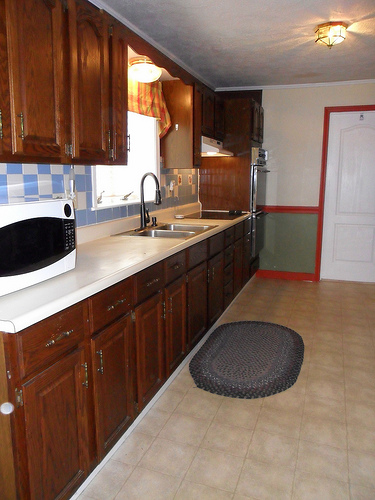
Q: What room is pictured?
A: It is a kitchen.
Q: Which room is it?
A: It is a kitchen.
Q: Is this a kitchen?
A: Yes, it is a kitchen.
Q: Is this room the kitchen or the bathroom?
A: It is the kitchen.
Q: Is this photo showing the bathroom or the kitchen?
A: It is showing the kitchen.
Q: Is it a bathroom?
A: No, it is a kitchen.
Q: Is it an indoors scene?
A: Yes, it is indoors.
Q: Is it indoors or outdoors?
A: It is indoors.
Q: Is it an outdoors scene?
A: No, it is indoors.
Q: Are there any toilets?
A: No, there are no toilets.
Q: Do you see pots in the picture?
A: No, there are no pots.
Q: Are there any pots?
A: No, there are no pots.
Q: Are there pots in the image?
A: No, there are no pots.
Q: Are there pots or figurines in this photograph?
A: No, there are no pots or figurines.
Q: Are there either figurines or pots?
A: No, there are no pots or figurines.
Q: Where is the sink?
A: The sink is in the kitchen.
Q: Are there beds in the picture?
A: No, there are no beds.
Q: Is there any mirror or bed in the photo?
A: No, there are no beds or mirrors.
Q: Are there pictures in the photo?
A: No, there are no pictures.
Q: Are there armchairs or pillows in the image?
A: No, there are no pillows or armchairs.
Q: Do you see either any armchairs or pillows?
A: No, there are no pillows or armchairs.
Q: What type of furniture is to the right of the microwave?
A: The piece of furniture is a drawer.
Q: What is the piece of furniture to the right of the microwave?
A: The piece of furniture is a drawer.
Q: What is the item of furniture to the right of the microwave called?
A: The piece of furniture is a drawer.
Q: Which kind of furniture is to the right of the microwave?
A: The piece of furniture is a drawer.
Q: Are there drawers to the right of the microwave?
A: Yes, there is a drawer to the right of the microwave.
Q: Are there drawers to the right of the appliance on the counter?
A: Yes, there is a drawer to the right of the microwave.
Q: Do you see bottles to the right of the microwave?
A: No, there is a drawer to the right of the microwave.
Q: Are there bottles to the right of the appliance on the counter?
A: No, there is a drawer to the right of the microwave.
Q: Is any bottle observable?
A: No, there are no bottles.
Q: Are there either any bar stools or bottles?
A: No, there are no bottles or bar stools.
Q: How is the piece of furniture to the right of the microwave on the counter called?
A: The piece of furniture is a drawer.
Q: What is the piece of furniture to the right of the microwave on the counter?
A: The piece of furniture is a drawer.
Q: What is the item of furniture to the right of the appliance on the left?
A: The piece of furniture is a drawer.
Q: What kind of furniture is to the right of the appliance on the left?
A: The piece of furniture is a drawer.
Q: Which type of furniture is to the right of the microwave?
A: The piece of furniture is a drawer.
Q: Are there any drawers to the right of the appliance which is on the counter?
A: Yes, there is a drawer to the right of the microwave.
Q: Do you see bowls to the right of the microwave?
A: No, there is a drawer to the right of the microwave.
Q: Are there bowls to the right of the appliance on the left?
A: No, there is a drawer to the right of the microwave.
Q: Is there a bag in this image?
A: No, there are no bags.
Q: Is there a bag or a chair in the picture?
A: No, there are no bags or chairs.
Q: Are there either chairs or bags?
A: No, there are no bags or chairs.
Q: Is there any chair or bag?
A: No, there are no bags or chairs.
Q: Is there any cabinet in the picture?
A: Yes, there is a cabinet.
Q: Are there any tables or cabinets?
A: Yes, there is a cabinet.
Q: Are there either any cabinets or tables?
A: Yes, there is a cabinet.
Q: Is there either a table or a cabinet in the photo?
A: Yes, there is a cabinet.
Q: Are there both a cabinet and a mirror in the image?
A: No, there is a cabinet but no mirrors.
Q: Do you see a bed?
A: No, there are no beds.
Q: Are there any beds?
A: No, there are no beds.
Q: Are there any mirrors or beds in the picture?
A: No, there are no beds or mirrors.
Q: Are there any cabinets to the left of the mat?
A: Yes, there is a cabinet to the left of the mat.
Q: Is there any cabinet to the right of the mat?
A: No, the cabinet is to the left of the mat.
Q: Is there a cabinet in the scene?
A: Yes, there is a cabinet.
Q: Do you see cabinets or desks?
A: Yes, there is a cabinet.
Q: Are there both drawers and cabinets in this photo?
A: Yes, there are both a cabinet and a drawer.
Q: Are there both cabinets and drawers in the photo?
A: Yes, there are both a cabinet and a drawer.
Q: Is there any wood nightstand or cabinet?
A: Yes, there is a wood cabinet.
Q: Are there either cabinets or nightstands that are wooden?
A: Yes, the cabinet is wooden.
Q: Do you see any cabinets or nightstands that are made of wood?
A: Yes, the cabinet is made of wood.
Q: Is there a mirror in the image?
A: No, there are no mirrors.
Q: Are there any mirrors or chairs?
A: No, there are no mirrors or chairs.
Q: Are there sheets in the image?
A: No, there are no sheets.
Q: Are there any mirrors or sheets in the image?
A: No, there are no sheets or mirrors.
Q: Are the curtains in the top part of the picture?
A: Yes, the curtains are in the top of the image.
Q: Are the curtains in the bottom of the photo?
A: No, the curtains are in the top of the image.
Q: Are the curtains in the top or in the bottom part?
A: The curtains are in the top of the image.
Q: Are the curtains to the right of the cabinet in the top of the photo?
A: Yes, the curtains are to the right of the cabinet.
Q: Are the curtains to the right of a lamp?
A: No, the curtains are to the right of the cabinet.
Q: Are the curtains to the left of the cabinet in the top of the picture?
A: No, the curtains are to the right of the cabinet.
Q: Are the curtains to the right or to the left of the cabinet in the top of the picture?
A: The curtains are to the right of the cabinet.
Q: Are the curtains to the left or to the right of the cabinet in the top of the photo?
A: The curtains are to the right of the cabinet.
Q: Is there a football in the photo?
A: No, there are no footballs.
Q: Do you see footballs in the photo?
A: No, there are no footballs.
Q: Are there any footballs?
A: No, there are no footballs.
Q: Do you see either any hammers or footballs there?
A: No, there are no footballs or hammers.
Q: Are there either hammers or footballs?
A: No, there are no footballs or hammers.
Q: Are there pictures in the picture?
A: No, there are no pictures.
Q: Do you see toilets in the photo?
A: No, there are no toilets.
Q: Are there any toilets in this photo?
A: No, there are no toilets.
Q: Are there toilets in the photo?
A: No, there are no toilets.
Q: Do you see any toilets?
A: No, there are no toilets.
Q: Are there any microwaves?
A: Yes, there is a microwave.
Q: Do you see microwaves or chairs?
A: Yes, there is a microwave.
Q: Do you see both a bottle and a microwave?
A: No, there is a microwave but no bottles.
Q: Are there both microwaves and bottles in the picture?
A: No, there is a microwave but no bottles.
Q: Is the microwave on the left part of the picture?
A: Yes, the microwave is on the left of the image.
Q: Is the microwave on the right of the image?
A: No, the microwave is on the left of the image.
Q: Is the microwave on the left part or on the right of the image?
A: The microwave is on the left of the image.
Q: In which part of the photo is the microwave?
A: The microwave is on the left of the image.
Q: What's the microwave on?
A: The microwave is on the counter.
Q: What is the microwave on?
A: The microwave is on the counter.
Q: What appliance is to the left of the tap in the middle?
A: The appliance is a microwave.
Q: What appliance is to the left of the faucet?
A: The appliance is a microwave.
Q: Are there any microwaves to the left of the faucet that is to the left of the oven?
A: Yes, there is a microwave to the left of the faucet.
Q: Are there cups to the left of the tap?
A: No, there is a microwave to the left of the tap.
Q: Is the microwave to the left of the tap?
A: Yes, the microwave is to the left of the tap.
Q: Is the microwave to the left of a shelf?
A: No, the microwave is to the left of the tap.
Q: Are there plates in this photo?
A: No, there are no plates.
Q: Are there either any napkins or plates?
A: No, there are no plates or napkins.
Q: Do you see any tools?
A: No, there are no tools.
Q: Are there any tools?
A: No, there are no tools.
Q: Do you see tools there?
A: No, there are no tools.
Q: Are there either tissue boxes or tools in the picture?
A: No, there are no tools or tissue boxes.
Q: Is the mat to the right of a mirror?
A: No, the mat is to the right of a cabinet.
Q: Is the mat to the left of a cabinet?
A: No, the mat is to the right of a cabinet.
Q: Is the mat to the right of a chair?
A: No, the mat is to the right of a cabinet.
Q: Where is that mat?
A: The mat is on the floor.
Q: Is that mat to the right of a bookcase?
A: No, the mat is to the right of a cabinet.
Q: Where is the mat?
A: The mat is on the floor.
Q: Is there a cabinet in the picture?
A: Yes, there is a cabinet.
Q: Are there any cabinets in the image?
A: Yes, there is a cabinet.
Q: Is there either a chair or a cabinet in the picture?
A: Yes, there is a cabinet.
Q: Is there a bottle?
A: No, there are no bottles.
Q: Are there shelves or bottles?
A: No, there are no bottles or shelves.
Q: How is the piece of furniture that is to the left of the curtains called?
A: The piece of furniture is a cabinet.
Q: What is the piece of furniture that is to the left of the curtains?
A: The piece of furniture is a cabinet.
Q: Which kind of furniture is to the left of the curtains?
A: The piece of furniture is a cabinet.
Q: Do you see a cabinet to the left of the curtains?
A: Yes, there is a cabinet to the left of the curtains.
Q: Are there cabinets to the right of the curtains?
A: No, the cabinet is to the left of the curtains.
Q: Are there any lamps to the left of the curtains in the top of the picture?
A: No, there is a cabinet to the left of the curtains.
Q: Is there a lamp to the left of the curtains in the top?
A: No, there is a cabinet to the left of the curtains.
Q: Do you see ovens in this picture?
A: Yes, there is an oven.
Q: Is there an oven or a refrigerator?
A: Yes, there is an oven.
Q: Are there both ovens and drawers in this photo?
A: Yes, there are both an oven and a drawer.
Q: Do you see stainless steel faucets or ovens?
A: Yes, there is a stainless steel oven.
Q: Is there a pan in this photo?
A: No, there are no pans.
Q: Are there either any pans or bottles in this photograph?
A: No, there are no pans or bottles.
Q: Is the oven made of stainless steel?
A: Yes, the oven is made of stainless steel.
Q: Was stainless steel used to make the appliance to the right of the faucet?
A: Yes, the oven is made of stainless steel.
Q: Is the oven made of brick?
A: No, the oven is made of stainless steel.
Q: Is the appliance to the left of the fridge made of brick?
A: No, the oven is made of stainless steel.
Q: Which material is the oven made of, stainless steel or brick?
A: The oven is made of stainless steel.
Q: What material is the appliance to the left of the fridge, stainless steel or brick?
A: The oven is made of stainless steel.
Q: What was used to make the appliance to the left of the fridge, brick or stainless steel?
A: The oven is made of stainless steel.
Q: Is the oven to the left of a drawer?
A: No, the oven is to the right of a drawer.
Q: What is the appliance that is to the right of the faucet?
A: The appliance is an oven.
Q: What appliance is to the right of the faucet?
A: The appliance is an oven.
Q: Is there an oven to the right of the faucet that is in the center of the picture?
A: Yes, there is an oven to the right of the tap.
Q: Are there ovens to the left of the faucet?
A: No, the oven is to the right of the faucet.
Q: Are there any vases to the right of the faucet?
A: No, there is an oven to the right of the faucet.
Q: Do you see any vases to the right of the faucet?
A: No, there is an oven to the right of the faucet.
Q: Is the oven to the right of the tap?
A: Yes, the oven is to the right of the tap.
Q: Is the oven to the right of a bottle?
A: No, the oven is to the right of the tap.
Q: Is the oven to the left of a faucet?
A: No, the oven is to the right of a faucet.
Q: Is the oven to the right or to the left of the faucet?
A: The oven is to the right of the faucet.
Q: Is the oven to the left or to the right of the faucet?
A: The oven is to the right of the faucet.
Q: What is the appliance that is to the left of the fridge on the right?
A: The appliance is an oven.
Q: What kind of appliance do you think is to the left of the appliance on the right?
A: The appliance is an oven.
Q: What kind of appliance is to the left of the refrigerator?
A: The appliance is an oven.